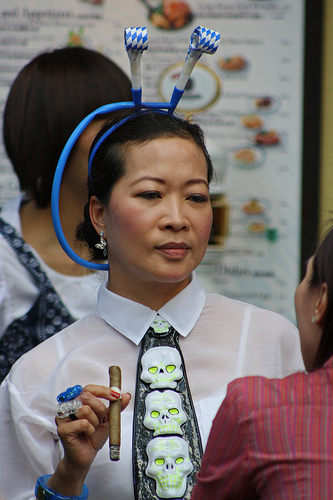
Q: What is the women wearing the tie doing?
A: Smoking a cigar.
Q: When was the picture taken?
A: During the day.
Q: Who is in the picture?
A: Three people.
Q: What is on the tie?
A: Three skulls.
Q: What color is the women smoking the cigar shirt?
A: White.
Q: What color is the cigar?
A: Brown.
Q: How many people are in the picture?
A: Three.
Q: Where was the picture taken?
A: Party.